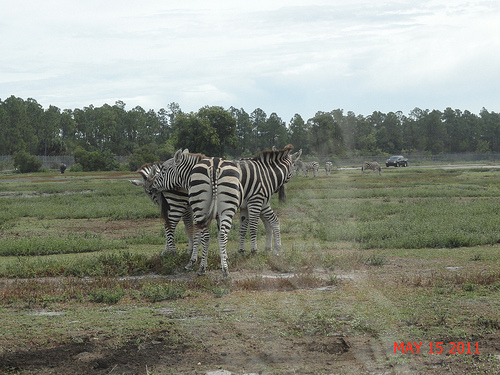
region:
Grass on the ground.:
[379, 202, 447, 263]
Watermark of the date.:
[388, 334, 488, 362]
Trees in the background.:
[309, 106, 440, 144]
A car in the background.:
[382, 149, 416, 173]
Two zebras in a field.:
[125, 134, 319, 274]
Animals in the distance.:
[294, 144, 389, 180]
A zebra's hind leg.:
[211, 209, 248, 287]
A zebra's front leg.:
[245, 186, 276, 263]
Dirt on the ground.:
[44, 339, 122, 368]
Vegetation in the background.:
[67, 146, 130, 182]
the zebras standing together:
[141, 148, 302, 271]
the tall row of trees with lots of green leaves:
[1, 100, 497, 156]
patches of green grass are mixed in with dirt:
[9, 178, 141, 283]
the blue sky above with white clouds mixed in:
[2, 3, 499, 110]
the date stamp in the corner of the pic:
[391, 343, 485, 361]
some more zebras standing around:
[298, 156, 335, 176]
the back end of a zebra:
[187, 160, 240, 267]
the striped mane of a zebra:
[250, 143, 295, 159]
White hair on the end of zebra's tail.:
[202, 194, 232, 220]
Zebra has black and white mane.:
[249, 138, 314, 174]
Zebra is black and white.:
[221, 160, 298, 184]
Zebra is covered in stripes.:
[217, 158, 317, 204]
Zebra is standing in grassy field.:
[181, 225, 354, 292]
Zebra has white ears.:
[171, 143, 190, 160]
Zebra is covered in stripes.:
[163, 158, 184, 183]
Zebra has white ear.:
[126, 175, 141, 191]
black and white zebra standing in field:
[184, 140, 306, 281]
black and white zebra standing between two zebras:
[146, 145, 298, 270]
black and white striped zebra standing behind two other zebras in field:
[123, 145, 285, 272]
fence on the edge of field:
[0, 151, 78, 175]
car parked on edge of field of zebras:
[383, 151, 410, 168]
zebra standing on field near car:
[359, 158, 386, 178]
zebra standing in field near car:
[322, 158, 334, 176]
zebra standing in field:
[290, 155, 322, 179]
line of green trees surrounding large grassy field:
[1, 93, 498, 171]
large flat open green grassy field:
[0, 160, 498, 373]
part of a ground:
[302, 273, 327, 324]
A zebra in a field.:
[154, 140, 242, 285]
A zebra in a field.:
[135, 156, 225, 264]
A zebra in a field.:
[222, 132, 289, 252]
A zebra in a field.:
[295, 155, 320, 178]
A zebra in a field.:
[324, 160, 331, 171]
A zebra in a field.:
[363, 157, 385, 177]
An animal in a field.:
[359, 160, 384, 176]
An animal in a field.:
[324, 161, 334, 172]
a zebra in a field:
[156, 146, 235, 276]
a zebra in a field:
[230, 143, 298, 256]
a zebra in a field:
[140, 164, 168, 206]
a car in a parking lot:
[386, 152, 410, 170]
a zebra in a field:
[319, 160, 337, 175]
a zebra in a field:
[362, 158, 382, 173]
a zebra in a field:
[306, 160, 322, 170]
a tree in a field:
[174, 114, 216, 156]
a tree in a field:
[198, 102, 235, 154]